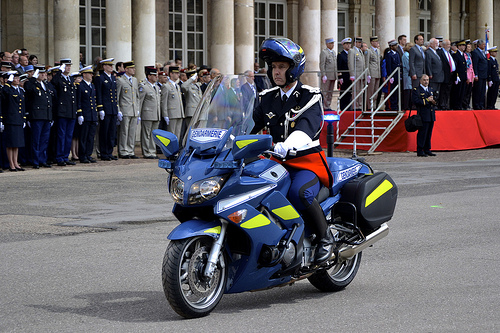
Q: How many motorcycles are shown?
A: One.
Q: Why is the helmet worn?
A: Safety.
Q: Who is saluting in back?
A: Military.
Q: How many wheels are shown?
A: Two.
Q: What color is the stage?
A: Red.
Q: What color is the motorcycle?
A: Blue and yellow.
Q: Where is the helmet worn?
A: Head.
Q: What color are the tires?
A: Black.